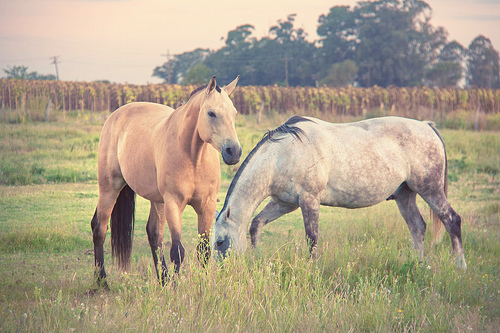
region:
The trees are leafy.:
[174, 5, 497, 89]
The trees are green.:
[161, 1, 493, 84]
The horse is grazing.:
[204, 110, 485, 281]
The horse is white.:
[203, 117, 485, 281]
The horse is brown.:
[72, 66, 251, 278]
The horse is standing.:
[80, 80, 249, 263]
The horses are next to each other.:
[62, 81, 492, 273]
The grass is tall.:
[14, 121, 499, 329]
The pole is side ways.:
[48, 48, 78, 80]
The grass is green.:
[15, 121, 497, 330]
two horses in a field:
[76, 63, 473, 291]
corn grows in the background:
[9, 73, 493, 122]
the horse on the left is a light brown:
[76, 71, 237, 291]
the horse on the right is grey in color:
[198, 96, 472, 291]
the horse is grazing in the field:
[151, 129, 492, 321]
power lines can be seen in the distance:
[42, 45, 467, 87]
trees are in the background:
[156, 7, 494, 108]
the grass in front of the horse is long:
[111, 233, 406, 332]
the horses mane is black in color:
[218, 114, 315, 221]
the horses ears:
[201, 74, 243, 95]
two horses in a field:
[90, 78, 463, 284]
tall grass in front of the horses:
[59, 232, 485, 332]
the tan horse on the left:
[85, 70, 239, 297]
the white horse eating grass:
[212, 114, 464, 281]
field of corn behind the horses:
[1, 80, 498, 122]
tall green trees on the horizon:
[174, 2, 499, 87]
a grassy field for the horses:
[5, 130, 497, 327]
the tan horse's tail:
[110, 190, 132, 268]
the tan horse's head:
[193, 73, 243, 165]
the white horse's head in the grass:
[207, 208, 247, 276]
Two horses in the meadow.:
[75, 70, 489, 303]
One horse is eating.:
[208, 113, 497, 268]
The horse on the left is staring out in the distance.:
[72, 75, 242, 278]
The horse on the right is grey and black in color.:
[225, 120, 473, 241]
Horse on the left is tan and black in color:
[85, 75, 240, 271]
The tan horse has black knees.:
[167, 230, 212, 275]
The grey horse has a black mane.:
[223, 103, 313, 195]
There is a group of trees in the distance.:
[145, 0, 497, 86]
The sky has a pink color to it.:
[6, 9, 316, 81]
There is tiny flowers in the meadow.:
[189, 230, 215, 247]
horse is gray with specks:
[304, 122, 379, 198]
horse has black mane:
[266, 129, 308, 139]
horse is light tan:
[130, 136, 164, 185]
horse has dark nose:
[218, 143, 233, 158]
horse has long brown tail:
[118, 198, 153, 268]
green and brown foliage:
[316, 93, 416, 128]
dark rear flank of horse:
[424, 175, 469, 254]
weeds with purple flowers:
[363, 265, 392, 297]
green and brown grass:
[8, 184, 52, 242]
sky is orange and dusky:
[92, 27, 141, 62]